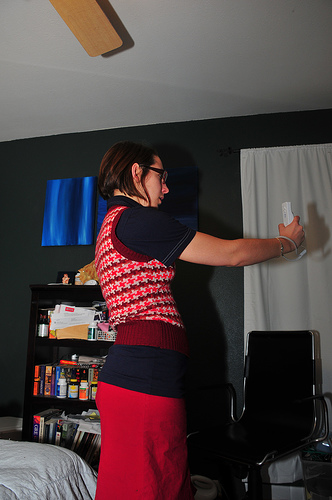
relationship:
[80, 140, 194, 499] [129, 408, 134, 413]
woman wearing red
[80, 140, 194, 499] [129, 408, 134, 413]
woman in red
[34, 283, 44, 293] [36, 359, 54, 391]
shelf with books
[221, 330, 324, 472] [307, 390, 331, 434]
black chair has silver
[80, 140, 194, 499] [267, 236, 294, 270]
woman wearing bracelet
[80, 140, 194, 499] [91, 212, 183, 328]
woman wearing ugly vest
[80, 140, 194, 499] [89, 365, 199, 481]
woman in skirt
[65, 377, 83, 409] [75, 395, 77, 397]
bottle of vitamins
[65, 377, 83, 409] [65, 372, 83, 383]
bottle with yellow top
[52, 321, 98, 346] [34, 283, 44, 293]
object on shelf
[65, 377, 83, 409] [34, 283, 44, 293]
bottle on shelf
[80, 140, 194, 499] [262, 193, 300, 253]
woman holding wii remote